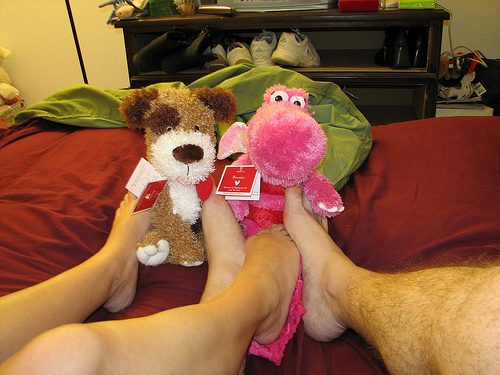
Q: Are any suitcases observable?
A: No, there are no suitcases.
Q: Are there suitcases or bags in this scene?
A: No, there are no suitcases or bags.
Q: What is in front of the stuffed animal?
A: The tag is in front of the stuffed animal.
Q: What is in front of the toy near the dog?
A: The tag is in front of the stuffed animal.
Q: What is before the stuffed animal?
A: The tag is in front of the stuffed animal.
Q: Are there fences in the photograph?
A: No, there are no fences.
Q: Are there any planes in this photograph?
A: No, there are no planes.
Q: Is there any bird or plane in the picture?
A: No, there are no airplanes or birds.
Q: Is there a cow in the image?
A: No, there are no cows.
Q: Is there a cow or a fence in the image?
A: No, there are no cows or fences.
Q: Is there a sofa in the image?
A: No, there are no sofas.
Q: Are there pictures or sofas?
A: No, there are no sofas or pictures.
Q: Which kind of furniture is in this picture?
A: The furniture is a shelf.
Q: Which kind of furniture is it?
A: The piece of furniture is a shelf.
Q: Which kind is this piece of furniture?
A: That is a shelf.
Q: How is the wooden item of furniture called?
A: The piece of furniture is a shelf.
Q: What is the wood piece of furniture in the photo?
A: The piece of furniture is a shelf.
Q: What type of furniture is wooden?
A: The furniture is a shelf.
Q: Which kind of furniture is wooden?
A: The furniture is a shelf.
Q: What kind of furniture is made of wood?
A: The furniture is a shelf.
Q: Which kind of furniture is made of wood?
A: The furniture is a shelf.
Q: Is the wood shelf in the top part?
A: Yes, the shelf is in the top of the image.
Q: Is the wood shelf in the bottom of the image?
A: No, the shelf is in the top of the image.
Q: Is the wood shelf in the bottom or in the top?
A: The shelf is in the top of the image.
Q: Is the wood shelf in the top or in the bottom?
A: The shelf is in the top of the image.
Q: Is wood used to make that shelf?
A: Yes, the shelf is made of wood.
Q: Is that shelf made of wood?
A: Yes, the shelf is made of wood.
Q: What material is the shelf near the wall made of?
A: The shelf is made of wood.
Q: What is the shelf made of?
A: The shelf is made of wood.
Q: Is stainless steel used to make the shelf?
A: No, the shelf is made of wood.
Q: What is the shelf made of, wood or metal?
A: The shelf is made of wood.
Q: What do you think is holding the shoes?
A: The shelf is holding the shoes.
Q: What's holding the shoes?
A: The shelf is holding the shoes.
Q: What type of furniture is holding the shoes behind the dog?
A: The piece of furniture is a shelf.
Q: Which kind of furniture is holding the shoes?
A: The piece of furniture is a shelf.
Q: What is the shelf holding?
A: The shelf is holding the shoes.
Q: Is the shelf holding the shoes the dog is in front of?
A: Yes, the shelf is holding the shoes.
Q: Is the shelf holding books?
A: No, the shelf is holding the shoes.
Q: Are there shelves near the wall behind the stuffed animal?
A: Yes, there is a shelf near the wall.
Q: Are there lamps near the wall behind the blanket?
A: No, there is a shelf near the wall.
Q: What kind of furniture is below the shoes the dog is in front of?
A: The piece of furniture is a shelf.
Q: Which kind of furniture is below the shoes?
A: The piece of furniture is a shelf.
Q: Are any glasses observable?
A: No, there are no glasses.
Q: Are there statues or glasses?
A: No, there are no glasses or statues.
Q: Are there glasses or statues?
A: No, there are no glasses or statues.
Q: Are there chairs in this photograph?
A: No, there are no chairs.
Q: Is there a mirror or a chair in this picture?
A: No, there are no chairs or mirrors.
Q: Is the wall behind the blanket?
A: Yes, the wall is behind the blanket.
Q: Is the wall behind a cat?
A: No, the wall is behind the blanket.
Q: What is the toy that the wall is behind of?
A: The toy is a stuffed animal.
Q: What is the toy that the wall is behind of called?
A: The toy is a stuffed animal.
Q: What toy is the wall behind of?
A: The wall is behind the stuffed animal.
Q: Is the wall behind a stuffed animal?
A: Yes, the wall is behind a stuffed animal.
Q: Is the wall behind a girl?
A: No, the wall is behind a stuffed animal.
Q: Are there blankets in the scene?
A: Yes, there is a blanket.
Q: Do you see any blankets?
A: Yes, there is a blanket.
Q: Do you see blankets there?
A: Yes, there is a blanket.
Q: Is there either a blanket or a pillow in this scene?
A: Yes, there is a blanket.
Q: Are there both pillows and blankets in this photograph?
A: No, there is a blanket but no pillows.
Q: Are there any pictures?
A: No, there are no pictures.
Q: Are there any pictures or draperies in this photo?
A: No, there are no pictures or draperies.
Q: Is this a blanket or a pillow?
A: This is a blanket.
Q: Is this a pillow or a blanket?
A: This is a blanket.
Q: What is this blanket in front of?
A: The blanket is in front of the wall.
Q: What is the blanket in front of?
A: The blanket is in front of the wall.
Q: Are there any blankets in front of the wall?
A: Yes, there is a blanket in front of the wall.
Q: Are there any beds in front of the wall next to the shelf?
A: No, there is a blanket in front of the wall.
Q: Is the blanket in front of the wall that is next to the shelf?
A: Yes, the blanket is in front of the wall.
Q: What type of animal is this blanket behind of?
A: The blanket is behind the dog.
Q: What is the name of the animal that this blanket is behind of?
A: The animal is a dog.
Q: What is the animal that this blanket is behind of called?
A: The animal is a dog.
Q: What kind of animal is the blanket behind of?
A: The blanket is behind the dog.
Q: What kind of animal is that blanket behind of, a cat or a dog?
A: The blanket is behind a dog.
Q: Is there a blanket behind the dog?
A: Yes, there is a blanket behind the dog.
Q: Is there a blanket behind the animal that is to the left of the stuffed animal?
A: Yes, there is a blanket behind the dog.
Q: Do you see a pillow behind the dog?
A: No, there is a blanket behind the dog.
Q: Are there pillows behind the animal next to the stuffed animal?
A: No, there is a blanket behind the dog.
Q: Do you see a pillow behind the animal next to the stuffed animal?
A: No, there is a blanket behind the dog.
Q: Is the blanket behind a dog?
A: Yes, the blanket is behind a dog.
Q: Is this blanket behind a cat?
A: No, the blanket is behind a dog.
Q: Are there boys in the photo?
A: No, there are no boys.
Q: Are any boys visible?
A: No, there are no boys.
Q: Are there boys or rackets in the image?
A: No, there are no boys or rackets.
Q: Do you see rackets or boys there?
A: No, there are no boys or rackets.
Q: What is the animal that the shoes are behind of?
A: The animal is a dog.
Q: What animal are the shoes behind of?
A: The shoes are behind the dog.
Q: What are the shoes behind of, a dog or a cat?
A: The shoes are behind a dog.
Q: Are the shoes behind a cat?
A: No, the shoes are behind the dog.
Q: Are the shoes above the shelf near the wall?
A: Yes, the shoes are above the shelf.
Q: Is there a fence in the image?
A: No, there are no fences.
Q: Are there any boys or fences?
A: No, there are no fences or boys.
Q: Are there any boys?
A: No, there are no boys.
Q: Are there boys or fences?
A: No, there are no boys or fences.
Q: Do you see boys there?
A: No, there are no boys.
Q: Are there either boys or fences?
A: No, there are no boys or fences.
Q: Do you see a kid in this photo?
A: No, there are no children.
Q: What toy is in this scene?
A: The toy is a stuffed animal.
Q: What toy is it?
A: The toy is a stuffed animal.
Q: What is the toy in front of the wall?
A: The toy is a stuffed animal.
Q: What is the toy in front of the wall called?
A: The toy is a stuffed animal.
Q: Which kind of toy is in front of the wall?
A: The toy is a stuffed animal.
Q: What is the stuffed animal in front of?
A: The stuffed animal is in front of the wall.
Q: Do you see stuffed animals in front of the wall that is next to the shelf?
A: Yes, there is a stuffed animal in front of the wall.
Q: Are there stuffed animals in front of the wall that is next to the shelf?
A: Yes, there is a stuffed animal in front of the wall.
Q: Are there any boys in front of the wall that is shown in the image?
A: No, there is a stuffed animal in front of the wall.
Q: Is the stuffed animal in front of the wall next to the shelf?
A: Yes, the stuffed animal is in front of the wall.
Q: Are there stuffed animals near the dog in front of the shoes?
A: Yes, there is a stuffed animal near the dog.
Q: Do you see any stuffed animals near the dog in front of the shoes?
A: Yes, there is a stuffed animal near the dog.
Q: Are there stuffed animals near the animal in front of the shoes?
A: Yes, there is a stuffed animal near the dog.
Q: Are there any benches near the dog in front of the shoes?
A: No, there is a stuffed animal near the dog.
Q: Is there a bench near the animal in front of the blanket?
A: No, there is a stuffed animal near the dog.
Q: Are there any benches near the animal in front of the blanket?
A: No, there is a stuffed animal near the dog.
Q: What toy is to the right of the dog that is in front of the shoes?
A: The toy is a stuffed animal.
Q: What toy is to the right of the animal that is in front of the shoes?
A: The toy is a stuffed animal.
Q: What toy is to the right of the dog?
A: The toy is a stuffed animal.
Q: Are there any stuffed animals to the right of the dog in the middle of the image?
A: Yes, there is a stuffed animal to the right of the dog.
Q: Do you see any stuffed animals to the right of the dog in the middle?
A: Yes, there is a stuffed animal to the right of the dog.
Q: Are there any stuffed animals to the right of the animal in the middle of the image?
A: Yes, there is a stuffed animal to the right of the dog.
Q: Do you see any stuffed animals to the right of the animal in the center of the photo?
A: Yes, there is a stuffed animal to the right of the dog.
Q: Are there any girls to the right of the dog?
A: No, there is a stuffed animal to the right of the dog.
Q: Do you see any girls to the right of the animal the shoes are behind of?
A: No, there is a stuffed animal to the right of the dog.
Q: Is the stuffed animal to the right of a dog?
A: Yes, the stuffed animal is to the right of a dog.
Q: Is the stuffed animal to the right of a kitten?
A: No, the stuffed animal is to the right of a dog.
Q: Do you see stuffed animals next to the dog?
A: Yes, there is a stuffed animal next to the dog.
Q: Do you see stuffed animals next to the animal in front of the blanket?
A: Yes, there is a stuffed animal next to the dog.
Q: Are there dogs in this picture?
A: Yes, there is a dog.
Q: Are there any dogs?
A: Yes, there is a dog.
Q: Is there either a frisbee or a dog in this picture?
A: Yes, there is a dog.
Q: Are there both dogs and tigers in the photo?
A: No, there is a dog but no tigers.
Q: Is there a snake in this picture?
A: No, there are no snakes.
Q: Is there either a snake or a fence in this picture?
A: No, there are no snakes or fences.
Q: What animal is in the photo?
A: The animal is a dog.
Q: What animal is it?
A: The animal is a dog.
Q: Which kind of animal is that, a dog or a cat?
A: That is a dog.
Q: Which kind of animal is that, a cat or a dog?
A: That is a dog.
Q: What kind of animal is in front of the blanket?
A: The animal is a dog.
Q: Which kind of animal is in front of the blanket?
A: The animal is a dog.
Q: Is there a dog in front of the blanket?
A: Yes, there is a dog in front of the blanket.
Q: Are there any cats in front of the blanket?
A: No, there is a dog in front of the blanket.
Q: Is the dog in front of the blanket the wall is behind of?
A: Yes, the dog is in front of the blanket.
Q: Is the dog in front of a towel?
A: No, the dog is in front of the blanket.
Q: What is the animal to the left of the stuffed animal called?
A: The animal is a dog.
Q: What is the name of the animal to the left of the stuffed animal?
A: The animal is a dog.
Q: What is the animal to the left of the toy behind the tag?
A: The animal is a dog.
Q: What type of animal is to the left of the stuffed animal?
A: The animal is a dog.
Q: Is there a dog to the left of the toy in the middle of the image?
A: Yes, there is a dog to the left of the stuffed animal.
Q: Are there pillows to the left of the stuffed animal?
A: No, there is a dog to the left of the stuffed animal.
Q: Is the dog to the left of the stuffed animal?
A: Yes, the dog is to the left of the stuffed animal.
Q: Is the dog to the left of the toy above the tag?
A: Yes, the dog is to the left of the stuffed animal.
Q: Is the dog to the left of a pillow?
A: No, the dog is to the left of the stuffed animal.